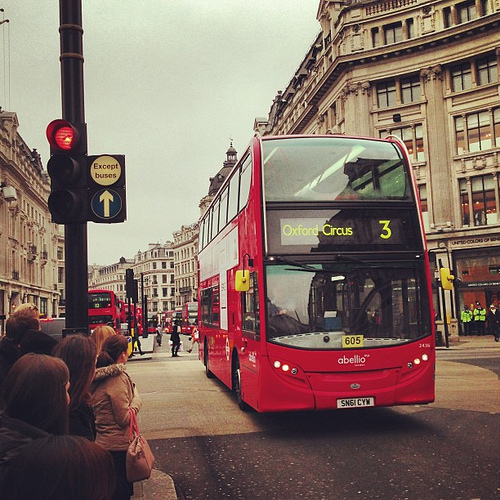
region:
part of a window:
[322, 313, 347, 341]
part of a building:
[163, 262, 166, 289]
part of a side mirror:
[236, 277, 252, 285]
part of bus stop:
[153, 452, 155, 475]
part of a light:
[416, 348, 428, 362]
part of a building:
[446, 186, 461, 231]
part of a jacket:
[121, 402, 150, 454]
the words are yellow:
[272, 214, 402, 247]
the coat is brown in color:
[88, 360, 155, 440]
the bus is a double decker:
[191, 137, 475, 411]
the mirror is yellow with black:
[230, 243, 263, 310]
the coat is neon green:
[458, 301, 476, 330]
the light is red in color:
[30, 104, 83, 164]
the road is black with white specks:
[284, 447, 421, 486]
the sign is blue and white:
[86, 186, 133, 227]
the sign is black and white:
[88, 151, 129, 186]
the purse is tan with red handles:
[116, 399, 178, 491]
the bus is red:
[174, 87, 491, 407]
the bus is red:
[211, 156, 438, 473]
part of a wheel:
[238, 380, 240, 400]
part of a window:
[288, 287, 325, 324]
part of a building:
[463, 245, 478, 272]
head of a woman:
[109, 337, 129, 376]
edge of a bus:
[260, 242, 276, 322]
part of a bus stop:
[157, 466, 162, 484]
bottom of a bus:
[336, 371, 346, 386]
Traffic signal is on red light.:
[33, 104, 102, 202]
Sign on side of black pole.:
[88, 138, 133, 253]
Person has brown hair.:
[102, 333, 127, 358]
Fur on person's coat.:
[100, 357, 130, 390]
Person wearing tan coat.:
[107, 382, 127, 432]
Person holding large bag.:
[102, 398, 182, 498]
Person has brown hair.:
[30, 354, 82, 430]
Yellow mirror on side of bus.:
[231, 265, 251, 295]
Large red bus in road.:
[176, 262, 401, 426]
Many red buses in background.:
[98, 291, 205, 358]